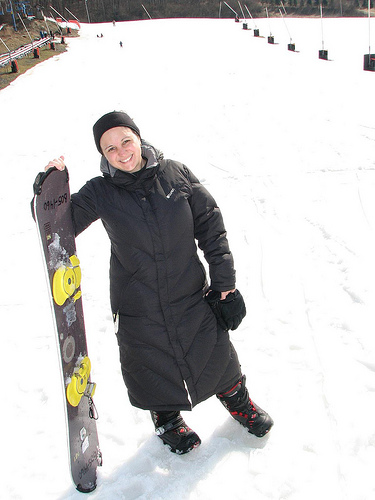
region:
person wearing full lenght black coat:
[36, 112, 270, 460]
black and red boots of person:
[141, 390, 271, 440]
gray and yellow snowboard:
[39, 173, 101, 494]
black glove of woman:
[206, 289, 248, 323]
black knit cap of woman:
[85, 107, 150, 137]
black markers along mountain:
[228, 10, 373, 72]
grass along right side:
[3, 19, 69, 74]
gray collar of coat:
[96, 142, 160, 175]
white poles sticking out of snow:
[48, 4, 371, 42]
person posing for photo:
[38, 116, 273, 451]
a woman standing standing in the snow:
[5, 84, 295, 493]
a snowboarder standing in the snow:
[9, 89, 279, 491]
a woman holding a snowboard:
[19, 80, 336, 497]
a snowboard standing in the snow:
[24, 68, 263, 497]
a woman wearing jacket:
[27, 81, 312, 498]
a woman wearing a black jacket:
[25, 105, 304, 496]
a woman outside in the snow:
[7, 68, 372, 423]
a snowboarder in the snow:
[16, 78, 362, 496]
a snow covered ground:
[146, 27, 367, 197]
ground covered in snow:
[197, 196, 370, 426]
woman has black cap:
[102, 96, 148, 153]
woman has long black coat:
[73, 177, 245, 396]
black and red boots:
[139, 395, 264, 441]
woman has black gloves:
[206, 283, 266, 339]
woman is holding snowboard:
[30, 188, 125, 498]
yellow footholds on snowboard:
[49, 247, 92, 403]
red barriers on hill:
[11, 29, 76, 78]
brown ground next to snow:
[1, 24, 70, 88]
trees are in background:
[73, 0, 273, 28]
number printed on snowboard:
[34, 185, 69, 221]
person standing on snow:
[20, 112, 290, 490]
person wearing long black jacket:
[49, 100, 264, 468]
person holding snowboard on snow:
[35, 122, 251, 498]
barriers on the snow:
[243, 15, 372, 82]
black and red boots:
[137, 370, 275, 454]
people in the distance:
[87, 10, 152, 67]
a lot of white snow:
[141, 16, 374, 171]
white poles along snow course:
[14, 10, 101, 59]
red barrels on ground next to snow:
[4, 38, 77, 102]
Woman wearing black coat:
[30, 111, 273, 455]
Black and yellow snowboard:
[32, 165, 103, 492]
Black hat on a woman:
[92, 112, 140, 154]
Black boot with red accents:
[147, 409, 200, 454]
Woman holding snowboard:
[29, 111, 273, 455]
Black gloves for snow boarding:
[203, 285, 245, 332]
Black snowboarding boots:
[215, 373, 273, 437]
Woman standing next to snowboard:
[31, 111, 273, 455]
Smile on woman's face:
[115, 154, 134, 165]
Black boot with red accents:
[218, 376, 273, 438]